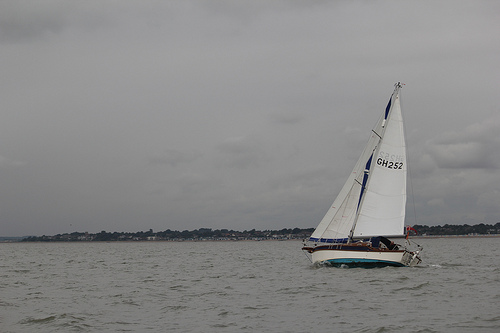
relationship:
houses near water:
[129, 235, 165, 241] [0, 236, 499, 331]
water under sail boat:
[0, 236, 499, 331] [295, 78, 430, 270]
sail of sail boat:
[300, 80, 417, 241] [295, 78, 430, 270]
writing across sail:
[376, 158, 404, 172] [300, 80, 417, 241]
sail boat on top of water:
[295, 78, 430, 270] [0, 236, 499, 331]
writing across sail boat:
[376, 158, 404, 172] [295, 78, 430, 270]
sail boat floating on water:
[295, 78, 430, 270] [0, 236, 499, 331]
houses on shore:
[129, 235, 165, 241] [78, 225, 311, 247]